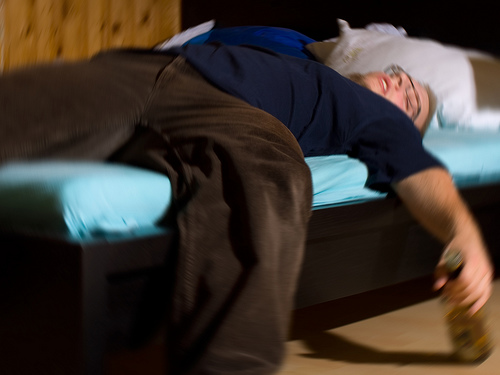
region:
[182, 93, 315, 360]
Brown pants in the photo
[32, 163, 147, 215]
Blue sheet in the photo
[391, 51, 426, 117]
Eyeglasses in the photo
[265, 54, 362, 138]
Blue shirt in the photo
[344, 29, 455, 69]
White pillow in the photo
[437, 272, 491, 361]
A bottle in the photo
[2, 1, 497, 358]
A bed in the photo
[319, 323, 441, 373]
A floor in the photo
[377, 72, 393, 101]
White teeth in the photo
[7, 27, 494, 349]
A man lying on the bed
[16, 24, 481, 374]
man laying on back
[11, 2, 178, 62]
wood wall behind head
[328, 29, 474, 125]
white case on pillow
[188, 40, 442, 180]
short sleeve blue shirt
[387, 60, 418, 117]
glasses on man's face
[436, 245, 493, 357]
bottle in man's hand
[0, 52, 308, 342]
brown pants on man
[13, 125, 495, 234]
blue sheet on bed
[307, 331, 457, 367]
shadow on top of floor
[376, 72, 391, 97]
teth in open mouth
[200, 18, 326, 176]
the shirt is blue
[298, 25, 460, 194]
the man is sleeping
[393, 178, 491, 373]
the man is holding a bottle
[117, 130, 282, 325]
the pants are brown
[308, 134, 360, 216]
the bed sheet is blue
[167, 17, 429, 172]
man sleeping on the bed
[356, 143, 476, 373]
the man holding a bottle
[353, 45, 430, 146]
the man is wearing eyeglasses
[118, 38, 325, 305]
the pants are brown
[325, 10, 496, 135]
the pillow is white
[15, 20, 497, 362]
Man sleeping on bed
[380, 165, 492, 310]
Lightly tanned left arm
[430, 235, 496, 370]
Hand grasping hand filled liquor bottle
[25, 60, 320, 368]
Brown denim jeans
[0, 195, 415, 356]
Dark wooden bed frame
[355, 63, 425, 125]
Young man wearing glasses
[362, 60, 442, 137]
Young man with blonde hair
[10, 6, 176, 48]
Light paneled wooden wall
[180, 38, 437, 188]
Dark blue t-shirt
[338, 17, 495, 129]
White plump pillow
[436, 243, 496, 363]
a bottle of beer in the mans left hand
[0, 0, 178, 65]
a wood paneled wall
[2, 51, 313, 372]
the man is wearing brown pants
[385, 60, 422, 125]
black framed eye glasses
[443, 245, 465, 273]
a plastic twist off top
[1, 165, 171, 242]
a blue bed sheet cover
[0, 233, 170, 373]
a brown wooden bed frame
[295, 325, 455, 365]
a shadow from the mans arm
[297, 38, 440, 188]
the mans shirt is blue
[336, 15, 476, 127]
a white pillow on the bed